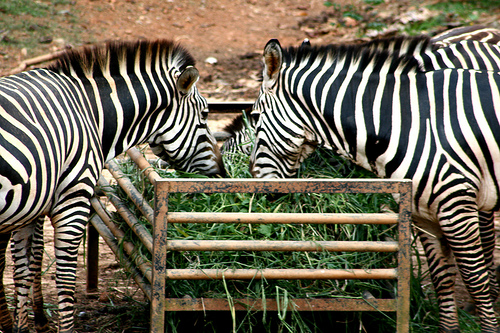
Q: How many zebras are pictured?
A: Two.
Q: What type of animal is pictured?
A: Zebra.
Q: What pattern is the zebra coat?
A: Striped.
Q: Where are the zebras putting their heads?
A: Into the grass.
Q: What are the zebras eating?
A: Grass.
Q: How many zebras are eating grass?
A: Two.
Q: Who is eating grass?
A: The zebras.